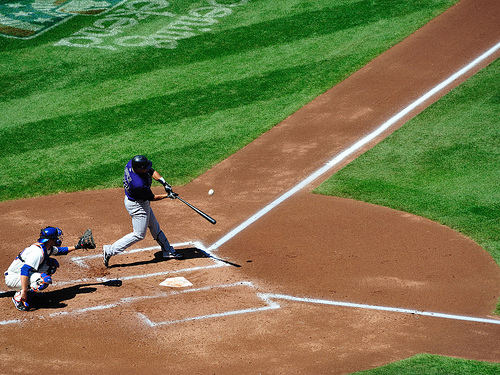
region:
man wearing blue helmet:
[43, 228, 53, 238]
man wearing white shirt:
[24, 249, 36, 263]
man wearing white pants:
[9, 272, 18, 287]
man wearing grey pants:
[131, 211, 142, 226]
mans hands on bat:
[163, 184, 177, 204]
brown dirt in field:
[283, 330, 331, 362]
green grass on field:
[403, 362, 448, 372]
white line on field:
[366, 304, 409, 315]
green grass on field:
[1, 2, 498, 251]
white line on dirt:
[212, 42, 497, 249]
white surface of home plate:
[160, 275, 193, 288]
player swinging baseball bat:
[101, 154, 214, 263]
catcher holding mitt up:
[5, 227, 94, 309]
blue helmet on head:
[37, 226, 62, 246]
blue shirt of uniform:
[122, 158, 153, 198]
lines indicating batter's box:
[125, 281, 278, 328]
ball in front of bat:
[177, 187, 219, 224]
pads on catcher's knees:
[33, 255, 60, 295]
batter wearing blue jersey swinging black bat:
[97, 136, 224, 268]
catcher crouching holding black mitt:
[2, 219, 105, 315]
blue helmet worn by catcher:
[37, 223, 65, 246]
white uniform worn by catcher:
[2, 245, 59, 300]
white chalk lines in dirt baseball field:
[3, 39, 495, 334]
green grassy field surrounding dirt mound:
[5, 0, 499, 371]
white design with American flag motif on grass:
[2, 1, 258, 69]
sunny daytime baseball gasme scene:
[5, 6, 498, 367]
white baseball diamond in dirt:
[157, 271, 192, 288]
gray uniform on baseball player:
[101, 194, 170, 252]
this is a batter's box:
[70, 230, 240, 280]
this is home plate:
[150, 267, 208, 297]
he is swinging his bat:
[96, 133, 243, 268]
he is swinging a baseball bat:
[85, 117, 247, 309]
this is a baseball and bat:
[164, 184, 240, 250]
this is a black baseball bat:
[158, 180, 223, 243]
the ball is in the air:
[200, 177, 222, 200]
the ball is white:
[193, 179, 222, 209]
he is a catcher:
[7, 203, 123, 328]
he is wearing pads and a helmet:
[4, 214, 114, 329]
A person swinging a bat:
[98, 140, 230, 280]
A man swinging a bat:
[98, 147, 217, 276]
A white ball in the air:
[202, 166, 220, 238]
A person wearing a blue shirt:
[100, 140, 160, 278]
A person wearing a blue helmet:
[102, 146, 157, 268]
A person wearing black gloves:
[152, 163, 181, 206]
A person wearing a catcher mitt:
[3, 210, 95, 321]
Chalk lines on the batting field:
[74, 217, 431, 327]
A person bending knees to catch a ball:
[3, 202, 98, 339]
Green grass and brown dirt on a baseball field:
[222, 25, 474, 195]